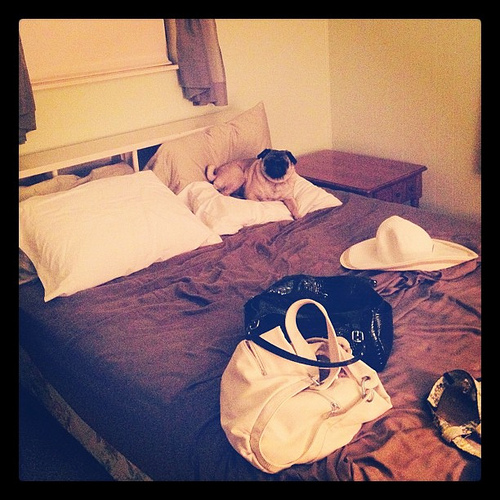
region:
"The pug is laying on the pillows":
[172, 109, 368, 249]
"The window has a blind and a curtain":
[9, 8, 256, 144]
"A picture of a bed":
[13, 100, 492, 494]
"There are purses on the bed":
[142, 255, 489, 486]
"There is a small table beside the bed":
[272, 105, 428, 230]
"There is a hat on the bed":
[318, 193, 489, 308]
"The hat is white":
[336, 193, 486, 300]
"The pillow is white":
[8, 161, 209, 303]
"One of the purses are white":
[217, 268, 396, 474]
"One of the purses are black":
[218, 266, 425, 473]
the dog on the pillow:
[193, 145, 314, 218]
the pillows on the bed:
[25, 156, 357, 270]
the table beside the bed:
[279, 143, 450, 222]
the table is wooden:
[294, 145, 435, 207]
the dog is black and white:
[203, 139, 303, 226]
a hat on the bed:
[330, 211, 485, 290]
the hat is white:
[331, 202, 476, 292]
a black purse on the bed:
[240, 272, 400, 361]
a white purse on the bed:
[212, 297, 412, 479]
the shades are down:
[20, 20, 180, 75]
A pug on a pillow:
[205, 144, 308, 217]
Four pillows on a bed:
[28, 94, 325, 313]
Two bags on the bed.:
[208, 265, 404, 465]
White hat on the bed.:
[326, 206, 478, 279]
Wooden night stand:
[272, 131, 432, 211]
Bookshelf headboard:
[21, 95, 255, 231]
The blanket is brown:
[35, 200, 478, 480]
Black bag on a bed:
[229, 262, 404, 380]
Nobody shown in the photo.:
[20, 20, 477, 477]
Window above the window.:
[17, 17, 184, 94]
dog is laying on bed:
[193, 140, 338, 238]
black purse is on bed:
[196, 246, 413, 376]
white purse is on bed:
[215, 287, 420, 474]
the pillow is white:
[18, 167, 215, 278]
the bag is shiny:
[239, 269, 423, 367]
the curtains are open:
[15, 21, 262, 133]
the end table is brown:
[292, 131, 435, 213]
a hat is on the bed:
[335, 204, 469, 288]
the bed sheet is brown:
[65, 196, 477, 483]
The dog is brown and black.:
[196, 140, 306, 222]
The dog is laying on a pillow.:
[188, 147, 338, 234]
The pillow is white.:
[182, 159, 348, 241]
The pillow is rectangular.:
[173, 149, 341, 242]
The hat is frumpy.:
[331, 211, 481, 288]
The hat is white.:
[333, 212, 479, 288]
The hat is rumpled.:
[327, 206, 488, 289]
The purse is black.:
[230, 256, 403, 375]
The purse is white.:
[212, 291, 396, 473]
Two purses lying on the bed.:
[41, 133, 439, 480]